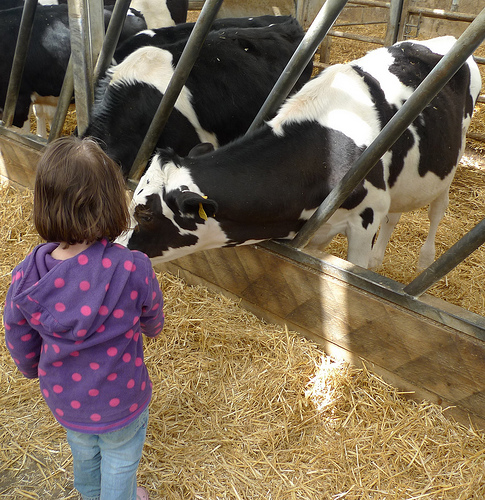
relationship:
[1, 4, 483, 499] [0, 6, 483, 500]
hay on floor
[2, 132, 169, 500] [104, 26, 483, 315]
girl feeding cow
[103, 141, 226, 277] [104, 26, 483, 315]
head of cow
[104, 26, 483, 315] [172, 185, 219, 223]
cow has ear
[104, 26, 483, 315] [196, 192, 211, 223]
cow has tag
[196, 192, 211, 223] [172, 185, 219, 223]
tag on ear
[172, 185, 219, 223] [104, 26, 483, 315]
ear of cow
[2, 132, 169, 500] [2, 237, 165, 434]
girl wearing hoodie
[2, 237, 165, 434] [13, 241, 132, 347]
hoodie has hood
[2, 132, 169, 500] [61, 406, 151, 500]
girl wearing jeans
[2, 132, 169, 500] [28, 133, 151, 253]
girl has hair